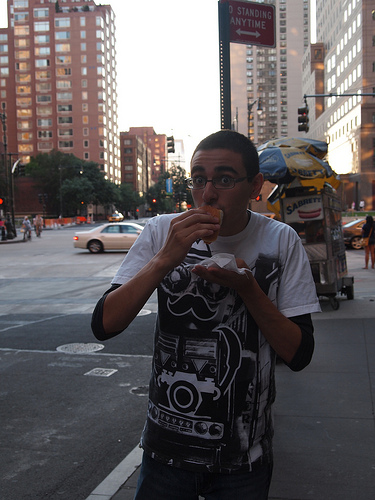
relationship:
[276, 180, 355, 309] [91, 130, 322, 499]
hotdog stand behind man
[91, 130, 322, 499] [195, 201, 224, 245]
man eating hot dog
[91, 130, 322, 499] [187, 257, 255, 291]
man has hand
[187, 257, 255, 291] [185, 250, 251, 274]
hand holding napkin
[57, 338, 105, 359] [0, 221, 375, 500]
sewer cover in middle of sidewalk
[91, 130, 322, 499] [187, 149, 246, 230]
man has face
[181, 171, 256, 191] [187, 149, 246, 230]
glasses worn on face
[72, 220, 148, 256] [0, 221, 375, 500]
car driving on sidewalk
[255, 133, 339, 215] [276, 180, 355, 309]
umbrellas above hotdog stand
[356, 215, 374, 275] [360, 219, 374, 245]
woman wearing shirt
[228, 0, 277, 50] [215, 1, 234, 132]
sign mounted on pole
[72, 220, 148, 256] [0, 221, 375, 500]
car turning on sidewalk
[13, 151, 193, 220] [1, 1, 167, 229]
trees next to buildings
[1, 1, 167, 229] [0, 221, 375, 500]
buildings on side of sidewalk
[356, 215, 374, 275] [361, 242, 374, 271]
woman wearing pants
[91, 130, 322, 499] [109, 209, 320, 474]
man wearing shirt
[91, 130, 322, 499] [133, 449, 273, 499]
man wearing jeans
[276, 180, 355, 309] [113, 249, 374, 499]
hotdog stand placed on sidewalk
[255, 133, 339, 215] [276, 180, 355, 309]
umbrellas on top of hotdog stand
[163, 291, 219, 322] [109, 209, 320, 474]
mustache printed on shirt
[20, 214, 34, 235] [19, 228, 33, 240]
person riding bicycle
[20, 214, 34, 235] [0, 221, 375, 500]
person riding bicycle in sidewalk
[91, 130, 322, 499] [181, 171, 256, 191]
man wearing glasses